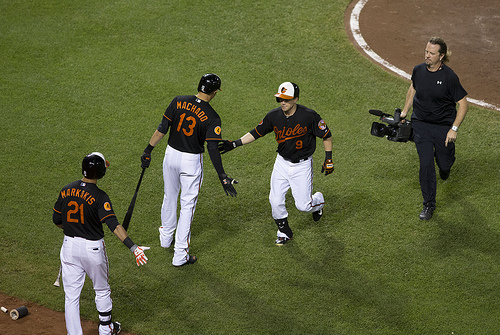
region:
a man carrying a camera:
[358, 30, 458, 233]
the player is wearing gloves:
[207, 72, 357, 227]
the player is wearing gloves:
[211, 128, 372, 200]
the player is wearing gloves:
[215, 159, 263, 211]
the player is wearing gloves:
[92, 217, 170, 288]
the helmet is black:
[167, 56, 229, 96]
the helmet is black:
[186, 61, 230, 89]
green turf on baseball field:
[109, 30, 176, 78]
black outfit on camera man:
[396, 54, 452, 177]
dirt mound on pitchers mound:
[382, 26, 465, 35]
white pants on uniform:
[75, 177, 307, 276]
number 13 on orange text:
[157, 107, 217, 129]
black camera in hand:
[369, 93, 458, 182]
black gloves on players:
[212, 138, 247, 209]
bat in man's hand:
[111, 183, 186, 257]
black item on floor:
[22, 292, 35, 332]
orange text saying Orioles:
[271, 112, 317, 158]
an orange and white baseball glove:
[127, 245, 149, 266]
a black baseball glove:
[216, 175, 241, 195]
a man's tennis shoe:
[173, 252, 202, 266]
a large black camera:
[367, 103, 413, 142]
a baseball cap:
[273, 78, 303, 105]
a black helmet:
[191, 72, 223, 96]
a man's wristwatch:
[450, 124, 461, 133]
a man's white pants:
[158, 148, 200, 263]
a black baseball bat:
[113, 157, 152, 232]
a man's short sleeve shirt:
[408, 62, 468, 142]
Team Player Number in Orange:
[62, 200, 92, 232]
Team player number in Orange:
[173, 109, 207, 142]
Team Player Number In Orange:
[288, 134, 308, 165]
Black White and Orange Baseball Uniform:
[148, 78, 233, 266]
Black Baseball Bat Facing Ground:
[119, 144, 147, 246]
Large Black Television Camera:
[360, 81, 425, 161]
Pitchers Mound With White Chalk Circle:
[308, 6, 496, 98]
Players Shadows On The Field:
[103, 254, 415, 334]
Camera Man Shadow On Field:
[413, 190, 498, 262]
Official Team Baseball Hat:
[256, 71, 307, 108]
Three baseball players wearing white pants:
[18, 67, 372, 254]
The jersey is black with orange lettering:
[165, 82, 212, 163]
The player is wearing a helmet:
[191, 68, 226, 101]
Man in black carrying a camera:
[364, 25, 481, 260]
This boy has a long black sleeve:
[193, 127, 246, 202]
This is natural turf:
[315, 235, 450, 333]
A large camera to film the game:
[362, 96, 422, 158]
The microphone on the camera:
[368, 103, 390, 124]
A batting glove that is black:
[312, 144, 339, 176]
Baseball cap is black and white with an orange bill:
[271, 75, 298, 101]